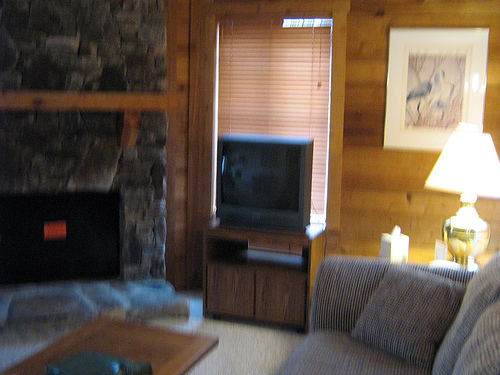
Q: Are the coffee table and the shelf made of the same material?
A: Yes, both the coffee table and the shelf are made of wood.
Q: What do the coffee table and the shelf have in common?
A: The material, both the coffee table and the shelf are wooden.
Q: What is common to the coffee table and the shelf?
A: The material, both the coffee table and the shelf are wooden.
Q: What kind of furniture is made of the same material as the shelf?
A: The coffee table is made of the same material as the shelf.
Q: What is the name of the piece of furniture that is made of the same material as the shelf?
A: The piece of furniture is a coffee table.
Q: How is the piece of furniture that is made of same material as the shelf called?
A: The piece of furniture is a coffee table.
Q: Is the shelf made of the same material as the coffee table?
A: Yes, both the shelf and the coffee table are made of wood.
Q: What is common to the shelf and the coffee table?
A: The material, both the shelf and the coffee table are wooden.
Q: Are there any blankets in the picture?
A: No, there are no blankets.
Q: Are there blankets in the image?
A: No, there are no blankets.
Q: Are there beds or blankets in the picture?
A: No, there are no blankets or beds.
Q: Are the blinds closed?
A: Yes, the blinds are closed.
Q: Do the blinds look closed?
A: Yes, the blinds are closed.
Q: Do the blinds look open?
A: No, the blinds are closed.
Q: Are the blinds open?
A: No, the blinds are closed.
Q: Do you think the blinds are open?
A: No, the blinds are closed.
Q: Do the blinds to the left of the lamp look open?
A: No, the blinds are closed.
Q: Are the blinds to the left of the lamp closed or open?
A: The blinds are closed.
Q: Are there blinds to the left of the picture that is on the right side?
A: Yes, there are blinds to the left of the picture.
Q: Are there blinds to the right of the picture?
A: No, the blinds are to the left of the picture.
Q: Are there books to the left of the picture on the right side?
A: No, there are blinds to the left of the picture.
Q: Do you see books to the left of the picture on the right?
A: No, there are blinds to the left of the picture.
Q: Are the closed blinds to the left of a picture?
A: Yes, the blinds are to the left of a picture.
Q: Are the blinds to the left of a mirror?
A: No, the blinds are to the left of a picture.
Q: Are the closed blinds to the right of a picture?
A: No, the blinds are to the left of a picture.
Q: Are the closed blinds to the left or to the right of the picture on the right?
A: The blinds are to the left of the picture.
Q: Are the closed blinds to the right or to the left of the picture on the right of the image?
A: The blinds are to the left of the picture.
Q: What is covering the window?
A: The blinds are covering the window.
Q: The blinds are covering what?
A: The blinds are covering the window.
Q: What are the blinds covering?
A: The blinds are covering the window.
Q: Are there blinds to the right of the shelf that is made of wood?
A: Yes, there are blinds to the right of the shelf.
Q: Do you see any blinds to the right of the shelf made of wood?
A: Yes, there are blinds to the right of the shelf.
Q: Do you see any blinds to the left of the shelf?
A: No, the blinds are to the right of the shelf.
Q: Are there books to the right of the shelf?
A: No, there are blinds to the right of the shelf.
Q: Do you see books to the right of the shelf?
A: No, there are blinds to the right of the shelf.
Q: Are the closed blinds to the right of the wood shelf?
A: Yes, the blinds are to the right of the shelf.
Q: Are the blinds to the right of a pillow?
A: No, the blinds are to the right of the shelf.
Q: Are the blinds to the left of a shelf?
A: No, the blinds are to the right of a shelf.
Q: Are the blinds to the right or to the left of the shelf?
A: The blinds are to the right of the shelf.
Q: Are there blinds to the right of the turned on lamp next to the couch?
A: No, the blinds are to the left of the lamp.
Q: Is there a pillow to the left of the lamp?
A: No, there are blinds to the left of the lamp.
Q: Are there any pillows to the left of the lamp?
A: No, there are blinds to the left of the lamp.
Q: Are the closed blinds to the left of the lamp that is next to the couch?
A: Yes, the blinds are to the left of the lamp.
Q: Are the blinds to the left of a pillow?
A: No, the blinds are to the left of the lamp.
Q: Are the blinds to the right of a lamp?
A: No, the blinds are to the left of a lamp.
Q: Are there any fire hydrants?
A: No, there are no fire hydrants.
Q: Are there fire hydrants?
A: No, there are no fire hydrants.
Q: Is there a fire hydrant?
A: No, there are no fire hydrants.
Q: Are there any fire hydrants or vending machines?
A: No, there are no fire hydrants or vending machines.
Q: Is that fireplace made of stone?
A: Yes, the fireplace is made of stone.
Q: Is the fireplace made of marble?
A: No, the fireplace is made of stone.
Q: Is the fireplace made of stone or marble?
A: The fireplace is made of stone.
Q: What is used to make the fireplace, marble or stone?
A: The fireplace is made of stone.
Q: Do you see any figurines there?
A: No, there are no figurines.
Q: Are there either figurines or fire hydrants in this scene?
A: No, there are no figurines or fire hydrants.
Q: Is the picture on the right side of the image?
A: Yes, the picture is on the right of the image.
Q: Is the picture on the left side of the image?
A: No, the picture is on the right of the image.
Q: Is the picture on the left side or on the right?
A: The picture is on the right of the image.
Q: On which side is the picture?
A: The picture is on the right of the image.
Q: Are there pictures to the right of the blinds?
A: Yes, there is a picture to the right of the blinds.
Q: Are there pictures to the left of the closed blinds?
A: No, the picture is to the right of the blinds.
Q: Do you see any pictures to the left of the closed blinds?
A: No, the picture is to the right of the blinds.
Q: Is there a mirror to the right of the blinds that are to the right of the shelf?
A: No, there is a picture to the right of the blinds.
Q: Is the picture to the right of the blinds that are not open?
A: Yes, the picture is to the right of the blinds.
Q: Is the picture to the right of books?
A: No, the picture is to the right of the blinds.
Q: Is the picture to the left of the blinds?
A: No, the picture is to the right of the blinds.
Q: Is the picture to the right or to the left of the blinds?
A: The picture is to the right of the blinds.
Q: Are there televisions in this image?
A: Yes, there is a television.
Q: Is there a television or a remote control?
A: Yes, there is a television.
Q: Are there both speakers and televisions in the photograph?
A: No, there is a television but no speakers.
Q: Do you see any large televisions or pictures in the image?
A: Yes, there is a large television.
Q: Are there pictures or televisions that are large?
A: Yes, the television is large.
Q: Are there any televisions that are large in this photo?
A: Yes, there is a large television.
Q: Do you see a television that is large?
A: Yes, there is a large television.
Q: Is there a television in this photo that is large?
A: Yes, there is a television that is large.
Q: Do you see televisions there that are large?
A: Yes, there is a television that is large.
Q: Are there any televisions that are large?
A: Yes, there is a television that is large.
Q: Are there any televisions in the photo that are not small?
A: Yes, there is a large television.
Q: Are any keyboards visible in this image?
A: No, there are no keyboards.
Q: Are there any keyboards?
A: No, there are no keyboards.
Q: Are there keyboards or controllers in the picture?
A: No, there are no keyboards or controllers.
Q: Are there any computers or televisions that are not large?
A: No, there is a television but it is large.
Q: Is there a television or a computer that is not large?
A: No, there is a television but it is large.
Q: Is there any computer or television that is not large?
A: No, there is a television but it is large.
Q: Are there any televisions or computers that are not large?
A: No, there is a television but it is large.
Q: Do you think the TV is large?
A: Yes, the TV is large.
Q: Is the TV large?
A: Yes, the TV is large.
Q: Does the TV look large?
A: Yes, the TV is large.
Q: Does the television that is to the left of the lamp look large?
A: Yes, the TV is large.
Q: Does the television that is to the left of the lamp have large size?
A: Yes, the TV is large.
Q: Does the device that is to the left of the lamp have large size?
A: Yes, the TV is large.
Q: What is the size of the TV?
A: The TV is large.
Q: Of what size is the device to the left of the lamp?
A: The TV is large.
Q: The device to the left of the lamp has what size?
A: The TV is large.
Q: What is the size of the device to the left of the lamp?
A: The TV is large.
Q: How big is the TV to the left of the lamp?
A: The TV is large.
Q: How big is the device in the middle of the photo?
A: The TV is large.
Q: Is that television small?
A: No, the television is large.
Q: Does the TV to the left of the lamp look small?
A: No, the television is large.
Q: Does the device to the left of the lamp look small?
A: No, the television is large.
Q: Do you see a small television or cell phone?
A: No, there is a television but it is large.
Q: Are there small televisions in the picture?
A: No, there is a television but it is large.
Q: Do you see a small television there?
A: No, there is a television but it is large.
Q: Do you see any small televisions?
A: No, there is a television but it is large.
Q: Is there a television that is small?
A: No, there is a television but it is large.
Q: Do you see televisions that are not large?
A: No, there is a television but it is large.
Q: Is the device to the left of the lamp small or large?
A: The TV is large.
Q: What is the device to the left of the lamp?
A: The device is a television.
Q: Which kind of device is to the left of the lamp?
A: The device is a television.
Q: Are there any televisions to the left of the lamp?
A: Yes, there is a television to the left of the lamp.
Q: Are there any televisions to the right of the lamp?
A: No, the television is to the left of the lamp.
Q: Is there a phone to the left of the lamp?
A: No, there is a television to the left of the lamp.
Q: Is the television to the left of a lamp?
A: Yes, the television is to the left of a lamp.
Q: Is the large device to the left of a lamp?
A: Yes, the television is to the left of a lamp.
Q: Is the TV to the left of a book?
A: No, the TV is to the left of a lamp.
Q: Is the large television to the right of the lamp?
A: No, the TV is to the left of the lamp.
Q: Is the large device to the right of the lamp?
A: No, the TV is to the left of the lamp.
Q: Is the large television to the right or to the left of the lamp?
A: The TV is to the left of the lamp.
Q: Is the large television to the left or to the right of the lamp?
A: The TV is to the left of the lamp.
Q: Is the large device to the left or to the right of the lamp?
A: The TV is to the left of the lamp.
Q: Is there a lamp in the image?
A: Yes, there is a lamp.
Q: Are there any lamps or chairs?
A: Yes, there is a lamp.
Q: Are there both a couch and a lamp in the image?
A: Yes, there are both a lamp and a couch.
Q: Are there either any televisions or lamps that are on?
A: Yes, the lamp is on.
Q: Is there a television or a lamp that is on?
A: Yes, the lamp is on.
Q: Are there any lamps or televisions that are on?
A: Yes, the lamp is on.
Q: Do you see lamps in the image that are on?
A: Yes, there is a lamp that is on.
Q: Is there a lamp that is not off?
A: Yes, there is a lamp that is on.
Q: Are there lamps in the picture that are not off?
A: Yes, there is a lamp that is on.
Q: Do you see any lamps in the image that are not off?
A: Yes, there is a lamp that is on .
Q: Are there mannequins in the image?
A: No, there are no mannequins.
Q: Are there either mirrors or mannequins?
A: No, there are no mannequins or mirrors.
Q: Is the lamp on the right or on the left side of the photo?
A: The lamp is on the right of the image.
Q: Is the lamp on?
A: Yes, the lamp is on.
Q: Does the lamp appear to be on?
A: Yes, the lamp is on.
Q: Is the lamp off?
A: No, the lamp is on.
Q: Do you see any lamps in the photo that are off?
A: No, there is a lamp but it is on.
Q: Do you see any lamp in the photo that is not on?
A: No, there is a lamp but it is on.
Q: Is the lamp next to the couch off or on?
A: The lamp is on.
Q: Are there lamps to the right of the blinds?
A: Yes, there is a lamp to the right of the blinds.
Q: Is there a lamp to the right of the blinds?
A: Yes, there is a lamp to the right of the blinds.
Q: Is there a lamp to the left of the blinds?
A: No, the lamp is to the right of the blinds.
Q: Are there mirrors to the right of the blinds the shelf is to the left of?
A: No, there is a lamp to the right of the blinds.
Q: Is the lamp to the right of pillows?
A: No, the lamp is to the right of the blinds.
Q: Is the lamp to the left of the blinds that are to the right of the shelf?
A: No, the lamp is to the right of the blinds.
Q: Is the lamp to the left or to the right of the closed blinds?
A: The lamp is to the right of the blinds.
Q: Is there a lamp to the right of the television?
A: Yes, there is a lamp to the right of the television.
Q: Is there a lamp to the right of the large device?
A: Yes, there is a lamp to the right of the television.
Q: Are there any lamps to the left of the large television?
A: No, the lamp is to the right of the television.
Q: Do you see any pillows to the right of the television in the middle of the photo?
A: No, there is a lamp to the right of the television.